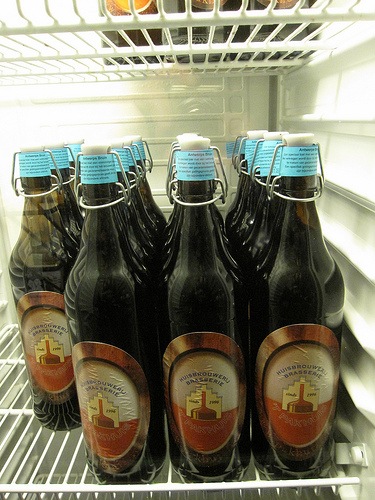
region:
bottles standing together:
[4, 118, 352, 479]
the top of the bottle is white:
[272, 121, 322, 168]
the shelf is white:
[5, 460, 345, 496]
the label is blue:
[69, 153, 123, 188]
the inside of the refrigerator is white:
[11, 79, 357, 225]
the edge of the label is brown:
[143, 321, 245, 369]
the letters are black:
[71, 151, 119, 186]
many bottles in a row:
[57, 122, 329, 460]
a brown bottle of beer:
[72, 140, 147, 480]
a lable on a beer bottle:
[172, 330, 241, 460]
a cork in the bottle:
[179, 134, 212, 152]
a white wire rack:
[5, 476, 359, 496]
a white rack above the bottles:
[96, 3, 345, 80]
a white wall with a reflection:
[84, 72, 273, 130]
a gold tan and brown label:
[172, 331, 243, 466]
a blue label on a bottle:
[174, 148, 219, 182]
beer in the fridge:
[3, 164, 343, 409]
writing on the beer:
[159, 359, 237, 404]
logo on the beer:
[169, 347, 238, 441]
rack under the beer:
[23, 424, 85, 478]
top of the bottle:
[165, 126, 232, 192]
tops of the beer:
[26, 110, 335, 229]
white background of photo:
[126, 83, 238, 124]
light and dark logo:
[172, 366, 234, 451]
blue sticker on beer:
[169, 147, 222, 183]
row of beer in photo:
[74, 125, 164, 230]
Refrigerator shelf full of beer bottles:
[13, 129, 341, 480]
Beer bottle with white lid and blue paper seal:
[164, 138, 246, 477]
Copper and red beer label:
[253, 315, 344, 453]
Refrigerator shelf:
[8, 436, 80, 494]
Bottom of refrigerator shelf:
[46, 2, 365, 87]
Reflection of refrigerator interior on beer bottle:
[60, 245, 106, 340]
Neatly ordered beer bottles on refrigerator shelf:
[8, 125, 349, 476]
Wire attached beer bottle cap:
[67, 141, 136, 225]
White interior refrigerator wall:
[132, 67, 360, 131]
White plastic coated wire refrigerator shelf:
[5, 427, 85, 498]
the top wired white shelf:
[0, 1, 373, 86]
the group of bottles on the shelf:
[7, 130, 344, 485]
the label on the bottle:
[253, 323, 339, 461]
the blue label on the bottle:
[278, 145, 318, 176]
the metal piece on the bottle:
[265, 143, 325, 200]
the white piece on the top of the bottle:
[282, 133, 313, 146]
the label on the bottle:
[162, 331, 247, 467]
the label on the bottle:
[71, 340, 149, 474]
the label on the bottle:
[16, 290, 77, 404]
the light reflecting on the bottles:
[8, 154, 344, 485]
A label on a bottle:
[161, 332, 249, 467]